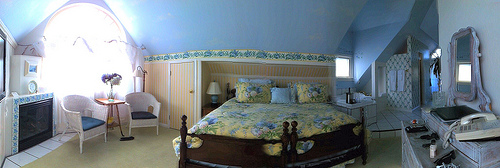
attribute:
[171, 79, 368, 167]
bed — yellow, made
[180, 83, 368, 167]
bed frame — brown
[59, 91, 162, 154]
chairs — white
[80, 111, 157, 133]
cushions — blue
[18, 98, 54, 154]
fireplace — black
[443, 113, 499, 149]
phone — white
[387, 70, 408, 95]
towels — hanging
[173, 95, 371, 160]
bedspread — yellow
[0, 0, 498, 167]
bedroom — clean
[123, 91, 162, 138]
chair — white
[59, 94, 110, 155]
chair — white